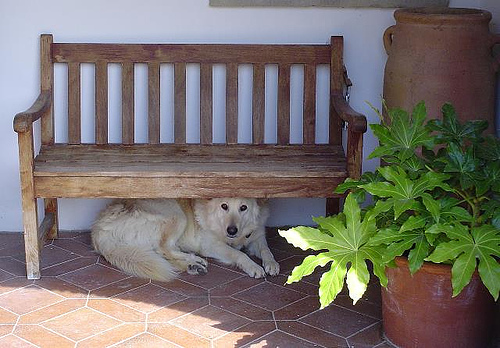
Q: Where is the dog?
A: Under bench.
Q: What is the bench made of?
A: Wood.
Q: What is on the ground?
A: Plant.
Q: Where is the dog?
A: Under the bench.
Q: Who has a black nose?
A: Dog.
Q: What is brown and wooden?
A: The bench.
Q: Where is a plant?
A: In a pot.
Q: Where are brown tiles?
A: On the floor.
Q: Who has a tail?
A: The dog.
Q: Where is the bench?
A: Against the wall.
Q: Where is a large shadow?
A: On the ground.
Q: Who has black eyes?
A: A dog.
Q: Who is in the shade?
A: A dog.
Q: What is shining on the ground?
A: Sunlight.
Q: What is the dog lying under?
A: A wooden bench.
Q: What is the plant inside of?
A: A large clay pot.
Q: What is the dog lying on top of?
A: A brick ground.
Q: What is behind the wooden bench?
A: A white wall.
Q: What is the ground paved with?
A: Red bricks.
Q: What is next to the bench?
A: A large pot.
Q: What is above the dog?
A: A wooden bench.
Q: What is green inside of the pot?
A: Leaves.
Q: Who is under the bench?
A: Dog.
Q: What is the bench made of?
A: Wood.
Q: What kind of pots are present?
A: Ceramic.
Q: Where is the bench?
A: By wall.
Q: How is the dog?
A: Seated.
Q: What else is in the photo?
A: Plant.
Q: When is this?
A: Daytime.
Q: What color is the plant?
A: Green.